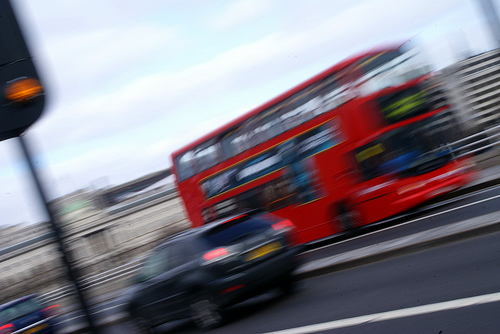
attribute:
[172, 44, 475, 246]
bus — blurry, red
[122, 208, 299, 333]
car — blurry, black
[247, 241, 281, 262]
license plate — yellow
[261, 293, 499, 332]
line — white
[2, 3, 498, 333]
photo — blurry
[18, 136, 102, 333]
post — black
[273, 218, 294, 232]
brake lights — red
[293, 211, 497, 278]
median — concrete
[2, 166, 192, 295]
garage — concrete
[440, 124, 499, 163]
fencing — gray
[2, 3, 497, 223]
sky — white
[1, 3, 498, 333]
picture — blurry